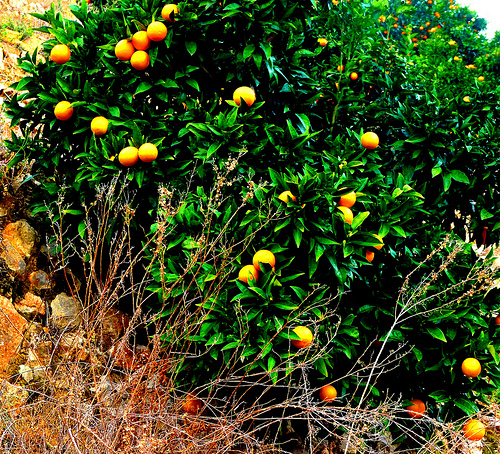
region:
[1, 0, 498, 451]
an orange tree filled with oranges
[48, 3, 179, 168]
oranges on a tree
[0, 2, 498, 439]
orange trees on a farm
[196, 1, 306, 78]
green leaves on the orange tree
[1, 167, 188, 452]
dry weeds on the side of the orange tree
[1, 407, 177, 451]
weeds on the ground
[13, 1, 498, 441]
bunches of oranges on the trees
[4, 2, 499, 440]
ripe oranges on green trees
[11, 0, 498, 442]
orange trees on the field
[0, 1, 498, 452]
a field containing orange trees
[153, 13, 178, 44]
bright orange on green bush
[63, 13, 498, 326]
green bush supporting oranges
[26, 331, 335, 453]
dead branches in front of bush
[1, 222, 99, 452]
large rocks in front of bush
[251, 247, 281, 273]
orange on green bush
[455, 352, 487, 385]
orange on green bush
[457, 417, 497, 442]
orange on green bush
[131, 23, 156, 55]
orange on green bush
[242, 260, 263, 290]
orange on green bush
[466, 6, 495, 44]
sky peering through green bush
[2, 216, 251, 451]
rusty orange and grey rocks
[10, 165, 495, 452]
dried up red and grey sticks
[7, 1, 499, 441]
leafy green citrus trees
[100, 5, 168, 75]
round orange clementine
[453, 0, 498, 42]
small piece of white grey sky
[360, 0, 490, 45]
taller blurry trees in the distance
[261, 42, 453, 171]
light reflecting off of green leaves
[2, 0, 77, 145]
orangey grey rocks in the background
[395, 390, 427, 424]
clementine in the shade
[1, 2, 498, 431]
dense cluster of clementine bushes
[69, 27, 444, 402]
oranges on trees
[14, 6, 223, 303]
plants on trees are orange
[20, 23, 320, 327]
green leaves on tree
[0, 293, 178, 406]
brown grass near tree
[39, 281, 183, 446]
grass near tree is thin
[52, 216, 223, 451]
grass near tree is dead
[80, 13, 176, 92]
cluster of oranges on tree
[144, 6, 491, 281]
leaves on tree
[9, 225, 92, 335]
rocks near orange tree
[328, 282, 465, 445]
tall thin strands of grass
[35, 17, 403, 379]
oranges growing on a tree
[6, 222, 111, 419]
rocks in front of tree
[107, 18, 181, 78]
four oranges clustered together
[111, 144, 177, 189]
Two round oranges together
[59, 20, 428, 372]
Many green leaves on tree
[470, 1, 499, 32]
clear sky in corner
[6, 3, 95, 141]
brown grass behind tree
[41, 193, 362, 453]
dead weeds in front of tree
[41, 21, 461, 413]
many oranges growing on a bush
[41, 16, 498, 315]
many green leaves on a bush